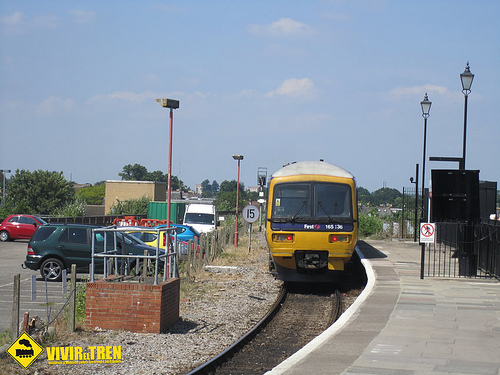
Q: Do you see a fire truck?
A: No, there are no fire trucks.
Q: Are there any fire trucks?
A: No, there are no fire trucks.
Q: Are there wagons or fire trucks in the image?
A: No, there are no fire trucks or wagons.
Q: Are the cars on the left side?
A: Yes, the cars are on the left of the image.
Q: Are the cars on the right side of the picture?
A: No, the cars are on the left of the image.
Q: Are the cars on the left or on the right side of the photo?
A: The cars are on the left of the image.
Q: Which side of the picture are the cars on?
A: The cars are on the left of the image.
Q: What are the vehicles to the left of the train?
A: The vehicles are cars.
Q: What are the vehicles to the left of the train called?
A: The vehicles are cars.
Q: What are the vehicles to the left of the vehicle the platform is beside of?
A: The vehicles are cars.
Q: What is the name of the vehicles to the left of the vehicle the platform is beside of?
A: The vehicles are cars.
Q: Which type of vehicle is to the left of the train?
A: The vehicles are cars.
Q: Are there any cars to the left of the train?
A: Yes, there are cars to the left of the train.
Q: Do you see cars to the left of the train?
A: Yes, there are cars to the left of the train.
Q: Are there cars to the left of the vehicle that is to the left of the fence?
A: Yes, there are cars to the left of the train.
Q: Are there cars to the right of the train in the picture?
A: No, the cars are to the left of the train.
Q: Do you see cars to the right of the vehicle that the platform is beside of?
A: No, the cars are to the left of the train.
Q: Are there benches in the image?
A: No, there are no benches.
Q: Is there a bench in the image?
A: No, there are no benches.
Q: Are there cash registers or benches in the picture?
A: No, there are no benches or cash registers.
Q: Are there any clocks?
A: No, there are no clocks.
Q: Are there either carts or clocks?
A: No, there are no clocks or carts.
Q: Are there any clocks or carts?
A: No, there are no clocks or carts.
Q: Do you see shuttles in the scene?
A: No, there are no shuttles.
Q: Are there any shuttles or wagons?
A: No, there are no shuttles or wagons.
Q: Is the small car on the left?
A: Yes, the car is on the left of the image.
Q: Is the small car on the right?
A: No, the car is on the left of the image.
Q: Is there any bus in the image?
A: No, there are no buses.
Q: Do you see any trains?
A: Yes, there is a train.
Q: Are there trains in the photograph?
A: Yes, there is a train.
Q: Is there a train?
A: Yes, there is a train.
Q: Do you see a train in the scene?
A: Yes, there is a train.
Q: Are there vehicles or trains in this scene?
A: Yes, there is a train.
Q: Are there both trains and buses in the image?
A: No, there is a train but no buses.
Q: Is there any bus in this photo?
A: No, there are no buses.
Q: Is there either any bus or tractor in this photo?
A: No, there are no buses or tractors.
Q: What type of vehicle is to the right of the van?
A: The vehicle is a train.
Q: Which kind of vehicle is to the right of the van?
A: The vehicle is a train.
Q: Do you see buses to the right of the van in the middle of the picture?
A: No, there is a train to the right of the van.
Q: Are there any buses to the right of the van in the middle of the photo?
A: No, there is a train to the right of the van.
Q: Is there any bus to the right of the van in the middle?
A: No, there is a train to the right of the van.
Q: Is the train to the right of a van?
A: Yes, the train is to the right of a van.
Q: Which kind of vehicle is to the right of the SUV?
A: The vehicle is a train.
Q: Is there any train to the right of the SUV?
A: Yes, there is a train to the right of the SUV.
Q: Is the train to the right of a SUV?
A: Yes, the train is to the right of a SUV.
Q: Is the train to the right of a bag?
A: No, the train is to the right of a SUV.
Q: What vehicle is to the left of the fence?
A: The vehicle is a train.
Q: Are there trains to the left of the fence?
A: Yes, there is a train to the left of the fence.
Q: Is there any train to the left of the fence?
A: Yes, there is a train to the left of the fence.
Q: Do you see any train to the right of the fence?
A: No, the train is to the left of the fence.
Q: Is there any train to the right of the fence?
A: No, the train is to the left of the fence.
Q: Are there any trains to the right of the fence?
A: No, the train is to the left of the fence.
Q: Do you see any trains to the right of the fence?
A: No, the train is to the left of the fence.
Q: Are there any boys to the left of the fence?
A: No, there is a train to the left of the fence.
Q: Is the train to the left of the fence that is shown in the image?
A: Yes, the train is to the left of the fence.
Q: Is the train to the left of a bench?
A: No, the train is to the left of the fence.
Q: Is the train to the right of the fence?
A: No, the train is to the left of the fence.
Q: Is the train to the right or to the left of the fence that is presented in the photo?
A: The train is to the left of the fence.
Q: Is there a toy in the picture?
A: No, there are no toys.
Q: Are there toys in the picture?
A: No, there are no toys.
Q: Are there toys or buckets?
A: No, there are no toys or buckets.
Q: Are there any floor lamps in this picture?
A: No, there are no floor lamps.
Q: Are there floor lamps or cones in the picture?
A: No, there are no floor lamps or cones.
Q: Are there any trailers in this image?
A: No, there are no trailers.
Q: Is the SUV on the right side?
A: No, the SUV is on the left of the image.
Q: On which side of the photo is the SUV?
A: The SUV is on the left of the image.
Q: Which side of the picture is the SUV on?
A: The SUV is on the left of the image.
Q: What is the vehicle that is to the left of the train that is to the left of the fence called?
A: The vehicle is a SUV.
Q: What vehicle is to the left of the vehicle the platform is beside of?
A: The vehicle is a SUV.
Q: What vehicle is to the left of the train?
A: The vehicle is a SUV.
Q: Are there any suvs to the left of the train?
A: Yes, there is a SUV to the left of the train.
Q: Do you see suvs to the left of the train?
A: Yes, there is a SUV to the left of the train.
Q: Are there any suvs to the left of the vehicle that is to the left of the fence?
A: Yes, there is a SUV to the left of the train.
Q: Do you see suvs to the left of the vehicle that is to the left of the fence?
A: Yes, there is a SUV to the left of the train.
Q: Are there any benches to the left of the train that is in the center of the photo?
A: No, there is a SUV to the left of the train.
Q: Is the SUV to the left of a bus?
A: No, the SUV is to the left of the train.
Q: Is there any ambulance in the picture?
A: No, there are no ambulances.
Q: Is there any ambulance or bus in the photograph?
A: No, there are no ambulances or buses.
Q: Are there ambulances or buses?
A: No, there are no ambulances or buses.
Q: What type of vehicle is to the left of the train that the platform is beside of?
A: The vehicle is a van.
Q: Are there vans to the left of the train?
A: Yes, there is a van to the left of the train.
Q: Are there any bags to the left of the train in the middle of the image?
A: No, there is a van to the left of the train.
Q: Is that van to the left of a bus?
A: No, the van is to the left of the train.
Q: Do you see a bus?
A: No, there are no buses.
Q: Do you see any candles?
A: No, there are no candles.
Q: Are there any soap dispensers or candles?
A: No, there are no candles or soap dispensers.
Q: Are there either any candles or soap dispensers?
A: No, there are no candles or soap dispensers.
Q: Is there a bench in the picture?
A: No, there are no benches.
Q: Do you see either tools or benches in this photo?
A: No, there are no benches or tools.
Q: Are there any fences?
A: Yes, there is a fence.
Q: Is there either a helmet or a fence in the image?
A: Yes, there is a fence.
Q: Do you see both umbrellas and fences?
A: No, there is a fence but no umbrellas.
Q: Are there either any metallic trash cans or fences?
A: Yes, there is a metal fence.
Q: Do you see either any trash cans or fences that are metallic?
A: Yes, the fence is metallic.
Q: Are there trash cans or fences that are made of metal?
A: Yes, the fence is made of metal.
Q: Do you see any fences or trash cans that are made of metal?
A: Yes, the fence is made of metal.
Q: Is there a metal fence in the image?
A: Yes, there is a metal fence.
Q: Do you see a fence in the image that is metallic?
A: Yes, there is a fence that is metallic.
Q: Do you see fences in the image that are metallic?
A: Yes, there is a fence that is metallic.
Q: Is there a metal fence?
A: Yes, there is a fence that is made of metal.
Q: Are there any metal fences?
A: Yes, there is a fence that is made of metal.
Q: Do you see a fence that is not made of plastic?
A: Yes, there is a fence that is made of metal.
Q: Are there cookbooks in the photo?
A: No, there are no cookbooks.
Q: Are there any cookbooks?
A: No, there are no cookbooks.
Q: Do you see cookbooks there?
A: No, there are no cookbooks.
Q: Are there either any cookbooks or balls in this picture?
A: No, there are no cookbooks or balls.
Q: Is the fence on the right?
A: Yes, the fence is on the right of the image.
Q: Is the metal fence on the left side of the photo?
A: No, the fence is on the right of the image.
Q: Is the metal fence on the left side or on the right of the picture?
A: The fence is on the right of the image.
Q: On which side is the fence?
A: The fence is on the right of the image.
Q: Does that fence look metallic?
A: Yes, the fence is metallic.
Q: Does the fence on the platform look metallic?
A: Yes, the fence is metallic.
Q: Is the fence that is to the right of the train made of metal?
A: Yes, the fence is made of metal.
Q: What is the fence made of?
A: The fence is made of metal.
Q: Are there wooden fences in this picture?
A: No, there is a fence but it is metallic.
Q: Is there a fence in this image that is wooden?
A: No, there is a fence but it is metallic.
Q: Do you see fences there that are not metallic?
A: No, there is a fence but it is metallic.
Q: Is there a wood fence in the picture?
A: No, there is a fence but it is made of metal.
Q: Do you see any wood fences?
A: No, there is a fence but it is made of metal.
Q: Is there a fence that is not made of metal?
A: No, there is a fence but it is made of metal.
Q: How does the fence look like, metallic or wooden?
A: The fence is metallic.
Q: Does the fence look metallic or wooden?
A: The fence is metallic.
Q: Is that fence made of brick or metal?
A: The fence is made of metal.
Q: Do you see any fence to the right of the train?
A: Yes, there is a fence to the right of the train.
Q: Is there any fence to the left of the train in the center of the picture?
A: No, the fence is to the right of the train.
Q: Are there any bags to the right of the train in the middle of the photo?
A: No, there is a fence to the right of the train.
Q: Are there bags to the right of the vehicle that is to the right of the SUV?
A: No, there is a fence to the right of the train.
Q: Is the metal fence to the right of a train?
A: Yes, the fence is to the right of a train.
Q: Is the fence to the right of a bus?
A: No, the fence is to the right of a train.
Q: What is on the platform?
A: The fence is on the platform.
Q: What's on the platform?
A: The fence is on the platform.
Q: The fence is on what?
A: The fence is on the platform.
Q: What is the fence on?
A: The fence is on the platform.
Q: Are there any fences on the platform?
A: Yes, there is a fence on the platform.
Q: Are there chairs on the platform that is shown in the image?
A: No, there is a fence on the platform.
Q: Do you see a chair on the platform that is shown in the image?
A: No, there is a fence on the platform.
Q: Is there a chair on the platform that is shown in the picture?
A: No, there is a fence on the platform.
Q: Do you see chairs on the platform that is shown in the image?
A: No, there is a fence on the platform.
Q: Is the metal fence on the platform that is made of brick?
A: Yes, the fence is on the platform.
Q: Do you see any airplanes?
A: No, there are no airplanes.